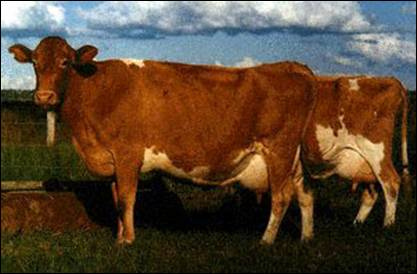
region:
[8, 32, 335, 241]
cow is brown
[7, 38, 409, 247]
two cows standing up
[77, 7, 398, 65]
clouds in blue sky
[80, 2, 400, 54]
clouds are white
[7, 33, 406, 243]
cows have some white spots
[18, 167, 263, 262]
grass underneath the cows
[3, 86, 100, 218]
fence in the background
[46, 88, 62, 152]
white fence post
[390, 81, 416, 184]
cow has a long tail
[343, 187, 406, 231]
cows legs are white and brown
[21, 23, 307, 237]
Brown cow in pasture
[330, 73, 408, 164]
Brown cow in pasture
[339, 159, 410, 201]
Pink utters on brown cow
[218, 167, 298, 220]
Pink utters on brown cow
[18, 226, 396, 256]
short grass under cows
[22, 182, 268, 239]
brown step by cows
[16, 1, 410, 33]
white clouds in blue sky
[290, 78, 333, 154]
tail of cow hanging off rear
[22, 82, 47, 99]
pink nose of brown cow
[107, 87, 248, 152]
thick brown hyde of cow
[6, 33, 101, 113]
head of a milk cow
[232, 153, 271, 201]
cow udder full of milk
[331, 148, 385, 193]
cow udder engorged with milk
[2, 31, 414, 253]
two brown and white milk cows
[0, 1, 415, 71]
clouds in the sky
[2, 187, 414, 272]
grass pasture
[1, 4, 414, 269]
two milk cows in a grass pasture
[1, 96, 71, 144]
pasture fencing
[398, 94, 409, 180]
brown and white cow tail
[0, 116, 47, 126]
fencing wire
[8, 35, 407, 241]
sides of two cows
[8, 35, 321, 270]
cow standing on grass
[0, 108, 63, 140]
post of wire fence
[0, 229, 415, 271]
green grass on foreground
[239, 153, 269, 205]
nipple on cow udder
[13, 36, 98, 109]
face of brown cow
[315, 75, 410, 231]
back of cow with tail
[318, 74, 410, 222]
grown and white cow fur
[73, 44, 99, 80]
ear with shadow underneath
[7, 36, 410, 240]
two cows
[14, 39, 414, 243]
the cows are standing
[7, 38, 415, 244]
the cows are brown and white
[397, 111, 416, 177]
the cows tail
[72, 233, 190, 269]
the grass is short and green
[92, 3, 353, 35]
a white cloud in the sky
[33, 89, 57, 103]
the cows nose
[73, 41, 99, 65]
the cows ear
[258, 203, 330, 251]
the cows back legs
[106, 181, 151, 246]
the cows front legs